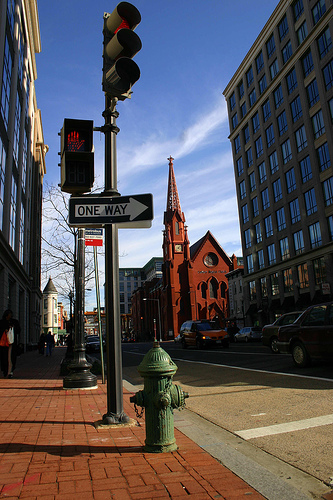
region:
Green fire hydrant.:
[129, 342, 190, 453]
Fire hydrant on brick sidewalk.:
[127, 342, 191, 459]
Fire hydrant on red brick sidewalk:
[128, 343, 190, 456]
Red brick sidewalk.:
[16, 402, 89, 472]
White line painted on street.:
[233, 412, 331, 442]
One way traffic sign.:
[67, 194, 155, 224]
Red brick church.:
[161, 154, 232, 330]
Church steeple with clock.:
[162, 154, 191, 321]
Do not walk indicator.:
[59, 116, 95, 191]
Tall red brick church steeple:
[162, 154, 192, 330]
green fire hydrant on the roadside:
[135, 338, 187, 451]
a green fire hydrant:
[126, 337, 192, 460]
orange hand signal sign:
[56, 118, 91, 157]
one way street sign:
[60, 188, 159, 233]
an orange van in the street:
[173, 311, 236, 352]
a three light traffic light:
[97, 0, 145, 117]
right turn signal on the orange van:
[196, 331, 215, 342]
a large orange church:
[129, 137, 243, 346]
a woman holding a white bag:
[1, 298, 20, 380]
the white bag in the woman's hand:
[3, 321, 17, 350]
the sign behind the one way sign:
[77, 220, 105, 251]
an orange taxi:
[173, 313, 232, 356]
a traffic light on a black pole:
[53, 2, 155, 433]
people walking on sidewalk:
[1, 305, 60, 381]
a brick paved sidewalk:
[0, 344, 265, 497]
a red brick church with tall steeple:
[127, 149, 244, 343]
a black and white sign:
[62, 190, 157, 233]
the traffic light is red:
[90, 0, 168, 124]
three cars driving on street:
[169, 301, 331, 387]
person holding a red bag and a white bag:
[1, 307, 24, 381]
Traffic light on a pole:
[83, 0, 143, 428]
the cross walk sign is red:
[48, 113, 97, 196]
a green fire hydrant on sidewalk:
[125, 339, 198, 456]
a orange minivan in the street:
[178, 311, 233, 363]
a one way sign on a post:
[63, 187, 153, 441]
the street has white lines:
[214, 388, 330, 443]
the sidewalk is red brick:
[24, 412, 105, 495]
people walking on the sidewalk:
[29, 327, 57, 366]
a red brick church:
[134, 154, 230, 340]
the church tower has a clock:
[172, 238, 182, 255]